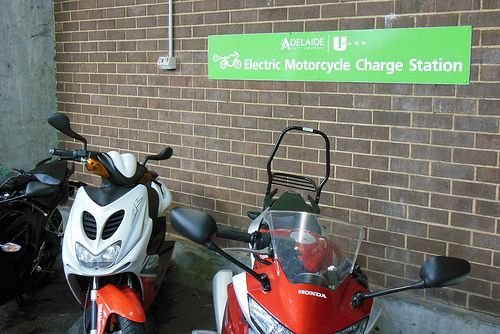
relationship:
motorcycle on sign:
[209, 51, 244, 73] [200, 24, 472, 88]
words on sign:
[240, 55, 468, 79] [213, 26, 449, 85]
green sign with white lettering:
[205, 22, 473, 87] [212, 36, 466, 76]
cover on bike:
[93, 281, 148, 332] [46, 110, 178, 332]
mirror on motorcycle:
[47, 112, 73, 136] [47, 112, 178, 333]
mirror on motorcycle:
[44, 102, 82, 135] [170, 124, 470, 334]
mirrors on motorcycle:
[416, 254, 474, 288] [170, 124, 472, 331]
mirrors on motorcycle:
[167, 205, 219, 245] [170, 124, 472, 331]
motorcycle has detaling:
[0, 147, 75, 331] [270, 285, 327, 315]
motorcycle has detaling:
[47, 112, 178, 333] [270, 285, 327, 315]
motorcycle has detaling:
[170, 124, 472, 331] [270, 285, 327, 315]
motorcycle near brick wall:
[170, 124, 470, 334] [53, 0, 499, 317]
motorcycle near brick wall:
[69, 143, 176, 320] [53, 0, 499, 317]